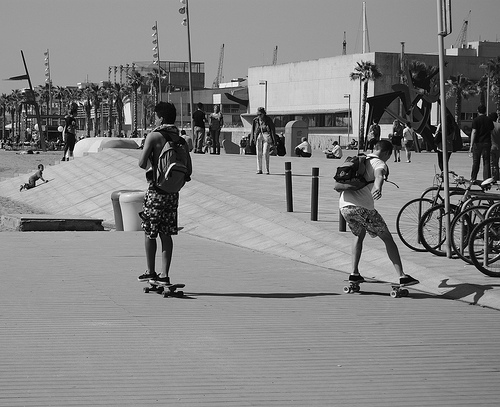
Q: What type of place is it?
A: It is a sidewalk.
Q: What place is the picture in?
A: It is at the sidewalk.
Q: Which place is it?
A: It is a sidewalk.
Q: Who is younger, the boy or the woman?
A: The boy is younger than the woman.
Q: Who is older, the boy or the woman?
A: The woman is older than the boy.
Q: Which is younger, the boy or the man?
A: The boy is younger than the man.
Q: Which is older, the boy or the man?
A: The man is older than the boy.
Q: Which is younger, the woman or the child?
A: The child is younger than the woman.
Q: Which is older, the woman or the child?
A: The woman is older than the child.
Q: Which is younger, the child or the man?
A: The child is younger than the man.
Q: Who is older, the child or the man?
A: The man is older than the child.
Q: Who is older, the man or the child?
A: The man is older than the child.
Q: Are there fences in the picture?
A: No, there are no fences.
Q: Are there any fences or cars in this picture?
A: No, there are no fences or cars.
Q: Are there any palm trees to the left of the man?
A: Yes, there is a palm tree to the left of the man.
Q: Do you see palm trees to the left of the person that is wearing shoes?
A: Yes, there is a palm tree to the left of the man.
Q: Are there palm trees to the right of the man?
A: No, the palm tree is to the left of the man.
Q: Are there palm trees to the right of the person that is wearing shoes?
A: No, the palm tree is to the left of the man.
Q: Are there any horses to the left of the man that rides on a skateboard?
A: No, there is a palm tree to the left of the man.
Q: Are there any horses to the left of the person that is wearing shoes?
A: No, there is a palm tree to the left of the man.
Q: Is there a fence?
A: No, there are no fences.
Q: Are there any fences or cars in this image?
A: No, there are no fences or cars.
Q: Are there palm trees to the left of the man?
A: Yes, there is a palm tree to the left of the man.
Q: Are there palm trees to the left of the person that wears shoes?
A: Yes, there is a palm tree to the left of the man.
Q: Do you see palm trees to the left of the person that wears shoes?
A: Yes, there is a palm tree to the left of the man.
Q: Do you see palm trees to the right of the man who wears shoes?
A: No, the palm tree is to the left of the man.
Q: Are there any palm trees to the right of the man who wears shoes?
A: No, the palm tree is to the left of the man.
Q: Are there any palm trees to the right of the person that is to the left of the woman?
A: No, the palm tree is to the left of the man.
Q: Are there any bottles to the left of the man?
A: No, there is a palm tree to the left of the man.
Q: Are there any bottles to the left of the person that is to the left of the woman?
A: No, there is a palm tree to the left of the man.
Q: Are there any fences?
A: No, there are no fences.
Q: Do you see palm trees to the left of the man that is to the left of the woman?
A: Yes, there is a palm tree to the left of the man.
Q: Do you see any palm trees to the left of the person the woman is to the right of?
A: Yes, there is a palm tree to the left of the man.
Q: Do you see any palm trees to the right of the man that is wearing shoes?
A: No, the palm tree is to the left of the man.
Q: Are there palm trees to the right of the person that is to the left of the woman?
A: No, the palm tree is to the left of the man.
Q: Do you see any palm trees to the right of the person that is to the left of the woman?
A: No, the palm tree is to the left of the man.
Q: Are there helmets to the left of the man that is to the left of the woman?
A: No, there is a palm tree to the left of the man.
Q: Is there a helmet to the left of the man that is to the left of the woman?
A: No, there is a palm tree to the left of the man.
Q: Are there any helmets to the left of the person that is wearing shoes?
A: No, there is a palm tree to the left of the man.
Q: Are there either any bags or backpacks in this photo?
A: Yes, there is a backpack.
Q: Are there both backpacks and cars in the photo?
A: No, there is a backpack but no cars.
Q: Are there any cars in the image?
A: No, there are no cars.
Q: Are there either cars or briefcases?
A: No, there are no cars or briefcases.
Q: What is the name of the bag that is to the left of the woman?
A: The bag is a backpack.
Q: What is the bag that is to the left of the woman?
A: The bag is a backpack.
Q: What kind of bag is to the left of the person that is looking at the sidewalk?
A: The bag is a backpack.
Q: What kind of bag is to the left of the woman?
A: The bag is a backpack.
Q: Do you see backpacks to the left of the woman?
A: Yes, there is a backpack to the left of the woman.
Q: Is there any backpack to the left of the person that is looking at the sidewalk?
A: Yes, there is a backpack to the left of the woman.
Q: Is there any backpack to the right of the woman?
A: No, the backpack is to the left of the woman.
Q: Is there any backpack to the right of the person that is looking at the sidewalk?
A: No, the backpack is to the left of the woman.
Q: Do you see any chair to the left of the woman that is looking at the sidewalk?
A: No, there is a backpack to the left of the woman.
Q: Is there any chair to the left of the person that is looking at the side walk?
A: No, there is a backpack to the left of the woman.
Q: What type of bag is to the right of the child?
A: The bag is a backpack.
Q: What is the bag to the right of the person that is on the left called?
A: The bag is a backpack.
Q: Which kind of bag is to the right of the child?
A: The bag is a backpack.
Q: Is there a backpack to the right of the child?
A: Yes, there is a backpack to the right of the child.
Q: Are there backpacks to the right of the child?
A: Yes, there is a backpack to the right of the child.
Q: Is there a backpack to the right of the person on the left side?
A: Yes, there is a backpack to the right of the child.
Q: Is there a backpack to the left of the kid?
A: No, the backpack is to the right of the kid.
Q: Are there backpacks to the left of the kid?
A: No, the backpack is to the right of the kid.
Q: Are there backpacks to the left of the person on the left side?
A: No, the backpack is to the right of the kid.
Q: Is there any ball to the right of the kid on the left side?
A: No, there is a backpack to the right of the child.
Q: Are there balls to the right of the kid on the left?
A: No, there is a backpack to the right of the child.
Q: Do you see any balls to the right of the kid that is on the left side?
A: No, there is a backpack to the right of the child.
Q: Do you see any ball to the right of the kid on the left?
A: No, there is a backpack to the right of the child.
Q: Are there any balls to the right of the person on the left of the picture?
A: No, there is a backpack to the right of the child.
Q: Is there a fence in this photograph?
A: No, there are no fences.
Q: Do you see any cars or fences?
A: No, there are no fences or cars.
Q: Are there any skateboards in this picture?
A: Yes, there is a skateboard.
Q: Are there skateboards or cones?
A: Yes, there is a skateboard.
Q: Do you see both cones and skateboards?
A: No, there is a skateboard but no cones.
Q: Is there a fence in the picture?
A: No, there are no fences.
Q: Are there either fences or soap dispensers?
A: No, there are no fences or soap dispensers.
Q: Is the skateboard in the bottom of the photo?
A: Yes, the skateboard is in the bottom of the image.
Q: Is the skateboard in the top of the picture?
A: No, the skateboard is in the bottom of the image.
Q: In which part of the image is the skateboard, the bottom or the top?
A: The skateboard is in the bottom of the image.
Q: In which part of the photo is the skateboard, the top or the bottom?
A: The skateboard is in the bottom of the image.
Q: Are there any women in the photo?
A: Yes, there is a woman.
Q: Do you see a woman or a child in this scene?
A: Yes, there is a woman.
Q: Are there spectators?
A: No, there are no spectators.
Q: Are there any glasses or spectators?
A: No, there are no spectators or glasses.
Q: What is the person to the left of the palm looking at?
A: The woman is looking at the sidewalk.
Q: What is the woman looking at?
A: The woman is looking at the sidewalk.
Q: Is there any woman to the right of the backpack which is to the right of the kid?
A: Yes, there is a woman to the right of the backpack.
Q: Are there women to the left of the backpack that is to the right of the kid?
A: No, the woman is to the right of the backpack.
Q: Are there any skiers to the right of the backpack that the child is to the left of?
A: No, there is a woman to the right of the backpack.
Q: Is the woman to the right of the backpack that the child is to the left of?
A: Yes, the woman is to the right of the backpack.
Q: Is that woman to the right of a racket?
A: No, the woman is to the right of the backpack.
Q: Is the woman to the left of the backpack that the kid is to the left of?
A: No, the woman is to the right of the backpack.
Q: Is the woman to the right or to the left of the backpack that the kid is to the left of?
A: The woman is to the right of the backpack.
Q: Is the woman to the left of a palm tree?
A: Yes, the woman is to the left of a palm tree.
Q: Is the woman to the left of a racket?
A: No, the woman is to the left of a palm tree.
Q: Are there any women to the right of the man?
A: Yes, there is a woman to the right of the man.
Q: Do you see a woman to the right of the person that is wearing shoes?
A: Yes, there is a woman to the right of the man.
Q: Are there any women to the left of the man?
A: No, the woman is to the right of the man.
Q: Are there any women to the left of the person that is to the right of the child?
A: No, the woman is to the right of the man.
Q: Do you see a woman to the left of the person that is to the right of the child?
A: No, the woman is to the right of the man.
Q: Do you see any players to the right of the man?
A: No, there is a woman to the right of the man.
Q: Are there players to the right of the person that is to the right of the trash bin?
A: No, there is a woman to the right of the man.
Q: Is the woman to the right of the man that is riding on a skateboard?
A: Yes, the woman is to the right of the man.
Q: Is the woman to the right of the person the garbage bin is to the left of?
A: Yes, the woman is to the right of the man.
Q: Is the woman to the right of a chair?
A: No, the woman is to the right of the man.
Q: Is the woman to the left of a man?
A: No, the woman is to the right of a man.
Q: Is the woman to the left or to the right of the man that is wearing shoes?
A: The woman is to the right of the man.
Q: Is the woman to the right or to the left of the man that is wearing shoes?
A: The woman is to the right of the man.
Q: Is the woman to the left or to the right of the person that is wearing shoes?
A: The woman is to the right of the man.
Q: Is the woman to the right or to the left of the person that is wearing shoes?
A: The woman is to the right of the man.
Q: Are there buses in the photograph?
A: No, there are no buses.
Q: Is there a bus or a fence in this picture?
A: No, there are no buses or fences.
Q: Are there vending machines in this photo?
A: No, there are no vending machines.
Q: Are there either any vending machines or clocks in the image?
A: No, there are no vending machines or clocks.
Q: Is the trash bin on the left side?
A: Yes, the trash bin is on the left of the image.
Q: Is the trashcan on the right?
A: No, the trashcan is on the left of the image.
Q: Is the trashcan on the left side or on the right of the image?
A: The trashcan is on the left of the image.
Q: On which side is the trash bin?
A: The trash bin is on the left of the image.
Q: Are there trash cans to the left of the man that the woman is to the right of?
A: Yes, there is a trash can to the left of the man.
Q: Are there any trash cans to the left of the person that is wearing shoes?
A: Yes, there is a trash can to the left of the man.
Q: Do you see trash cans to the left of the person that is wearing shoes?
A: Yes, there is a trash can to the left of the man.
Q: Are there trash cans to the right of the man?
A: No, the trash can is to the left of the man.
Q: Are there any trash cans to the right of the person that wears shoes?
A: No, the trash can is to the left of the man.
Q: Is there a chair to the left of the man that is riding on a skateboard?
A: No, there is a trash can to the left of the man.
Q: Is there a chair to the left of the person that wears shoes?
A: No, there is a trash can to the left of the man.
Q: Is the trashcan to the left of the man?
A: Yes, the trashcan is to the left of the man.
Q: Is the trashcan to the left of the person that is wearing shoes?
A: Yes, the trashcan is to the left of the man.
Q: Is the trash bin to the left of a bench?
A: No, the trash bin is to the left of the man.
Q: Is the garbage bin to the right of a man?
A: No, the garbage bin is to the left of a man.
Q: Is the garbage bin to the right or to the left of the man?
A: The garbage bin is to the left of the man.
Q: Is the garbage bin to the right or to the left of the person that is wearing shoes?
A: The garbage bin is to the left of the man.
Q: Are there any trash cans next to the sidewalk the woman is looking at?
A: Yes, there is a trash can next to the side walk.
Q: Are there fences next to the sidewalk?
A: No, there is a trash can next to the sidewalk.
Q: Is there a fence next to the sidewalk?
A: No, there is a trash can next to the sidewalk.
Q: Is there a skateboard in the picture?
A: Yes, there is a skateboard.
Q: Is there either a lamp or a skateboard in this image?
A: Yes, there is a skateboard.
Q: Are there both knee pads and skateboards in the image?
A: No, there is a skateboard but no knee pads.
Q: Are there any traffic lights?
A: No, there are no traffic lights.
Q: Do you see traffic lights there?
A: No, there are no traffic lights.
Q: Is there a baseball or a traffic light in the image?
A: No, there are no traffic lights or baseballs.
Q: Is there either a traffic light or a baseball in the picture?
A: No, there are no traffic lights or baseballs.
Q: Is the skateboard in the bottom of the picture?
A: Yes, the skateboard is in the bottom of the image.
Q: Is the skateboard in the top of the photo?
A: No, the skateboard is in the bottom of the image.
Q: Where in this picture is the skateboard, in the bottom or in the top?
A: The skateboard is in the bottom of the image.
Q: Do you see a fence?
A: No, there are no fences.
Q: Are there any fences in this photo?
A: No, there are no fences.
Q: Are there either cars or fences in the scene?
A: No, there are no fences or cars.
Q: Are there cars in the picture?
A: No, there are no cars.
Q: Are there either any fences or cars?
A: No, there are no cars or fences.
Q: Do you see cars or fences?
A: No, there are no cars or fences.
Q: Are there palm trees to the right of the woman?
A: Yes, there is a palm tree to the right of the woman.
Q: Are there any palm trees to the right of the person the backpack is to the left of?
A: Yes, there is a palm tree to the right of the woman.